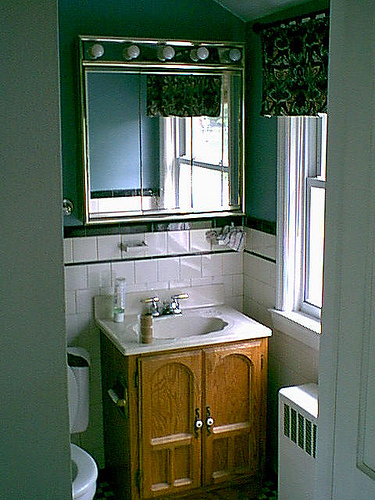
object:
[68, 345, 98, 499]
toilet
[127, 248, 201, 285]
tile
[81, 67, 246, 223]
mirror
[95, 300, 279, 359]
sink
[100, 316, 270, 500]
cabinet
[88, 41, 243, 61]
bulbs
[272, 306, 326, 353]
sill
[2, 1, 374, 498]
bathroom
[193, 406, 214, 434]
knobs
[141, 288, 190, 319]
faucet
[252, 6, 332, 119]
curtain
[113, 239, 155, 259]
dish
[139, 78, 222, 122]
reflection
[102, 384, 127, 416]
holder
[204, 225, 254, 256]
hand towel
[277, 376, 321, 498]
heater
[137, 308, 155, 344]
roll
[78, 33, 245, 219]
medicine cabinet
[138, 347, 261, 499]
doors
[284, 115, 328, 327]
bathroom window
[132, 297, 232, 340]
bathroom sink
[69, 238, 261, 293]
bathroom wall